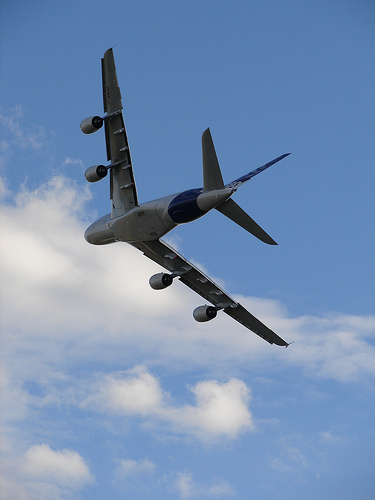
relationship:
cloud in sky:
[80, 366, 169, 423] [6, 0, 370, 497]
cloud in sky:
[80, 366, 169, 423] [255, 52, 331, 146]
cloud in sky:
[80, 366, 169, 423] [210, 10, 372, 105]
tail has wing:
[191, 125, 291, 249] [225, 150, 293, 187]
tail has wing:
[191, 125, 291, 249] [217, 194, 278, 245]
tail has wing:
[191, 125, 291, 249] [196, 121, 228, 187]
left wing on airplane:
[85, 46, 141, 207] [69, 36, 298, 360]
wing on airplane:
[129, 239, 289, 347] [69, 36, 298, 360]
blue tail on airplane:
[227, 148, 292, 192] [69, 36, 298, 360]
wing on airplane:
[196, 123, 224, 189] [69, 36, 298, 360]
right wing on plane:
[219, 201, 280, 254] [77, 40, 298, 356]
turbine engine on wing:
[78, 115, 104, 134] [101, 48, 136, 215]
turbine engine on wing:
[85, 164, 107, 181] [101, 48, 136, 215]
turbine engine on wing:
[149, 271, 173, 290] [129, 239, 289, 347]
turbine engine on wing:
[192, 305, 217, 322] [129, 239, 289, 347]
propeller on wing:
[77, 157, 118, 191] [97, 46, 139, 226]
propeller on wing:
[146, 267, 175, 291] [129, 239, 289, 347]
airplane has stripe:
[69, 36, 298, 360] [169, 186, 205, 222]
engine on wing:
[148, 270, 176, 290] [129, 239, 289, 347]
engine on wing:
[192, 303, 218, 324] [129, 239, 289, 347]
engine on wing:
[77, 112, 104, 135] [97, 46, 139, 226]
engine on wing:
[81, 160, 108, 180] [97, 46, 139, 226]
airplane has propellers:
[69, 36, 298, 360] [72, 103, 234, 341]